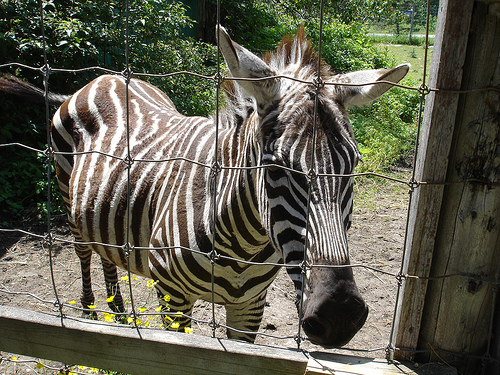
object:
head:
[251, 76, 369, 349]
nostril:
[301, 311, 326, 344]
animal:
[0, 22, 412, 348]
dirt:
[1, 272, 371, 350]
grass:
[395, 41, 424, 63]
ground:
[366, 32, 438, 54]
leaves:
[50, 12, 183, 79]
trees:
[31, 10, 176, 71]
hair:
[218, 21, 336, 99]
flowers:
[8, 272, 197, 375]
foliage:
[124, 16, 213, 62]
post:
[0, 302, 388, 375]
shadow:
[291, 334, 385, 374]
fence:
[0, 0, 498, 374]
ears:
[322, 62, 409, 106]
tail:
[0, 70, 75, 110]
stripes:
[75, 65, 297, 246]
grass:
[0, 212, 119, 264]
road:
[356, 30, 437, 50]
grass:
[368, 130, 414, 145]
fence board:
[0, 0, 500, 375]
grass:
[357, 167, 406, 209]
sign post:
[403, 3, 416, 43]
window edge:
[404, 163, 437, 244]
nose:
[295, 287, 370, 349]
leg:
[151, 279, 199, 332]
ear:
[213, 22, 280, 100]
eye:
[261, 154, 284, 173]